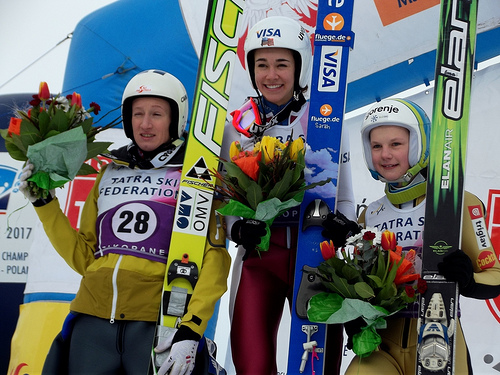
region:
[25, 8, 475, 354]
people are holding skis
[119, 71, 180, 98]
helmet on the head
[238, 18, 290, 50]
logo on the helmet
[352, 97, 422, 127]
logo on the helmet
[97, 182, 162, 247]
28 on the paper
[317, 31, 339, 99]
logo on the ski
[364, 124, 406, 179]
face of the boy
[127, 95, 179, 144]
face of the bow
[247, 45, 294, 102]
the boy is smiling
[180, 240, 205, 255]
the ski is yellow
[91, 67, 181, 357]
a person wearing a yellow jacket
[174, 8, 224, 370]
a yellow ski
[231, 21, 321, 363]
a lady wearing red pants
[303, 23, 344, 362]
a blue ski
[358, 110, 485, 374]
a girl wearing a white shirt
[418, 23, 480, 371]
a green ski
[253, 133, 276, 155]
a yellow flower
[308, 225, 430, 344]
a bouquet of flowers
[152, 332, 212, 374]
a white glove on the person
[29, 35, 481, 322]
three people holding flowers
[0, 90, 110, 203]
Flowers in the woman's right hand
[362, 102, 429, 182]
the woman is wearing a helmet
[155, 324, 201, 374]
The woman is wearing a glove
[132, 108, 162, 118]
The eyes of the woman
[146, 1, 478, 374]
Skis next to the women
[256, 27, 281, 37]
A Visa logo on the helmet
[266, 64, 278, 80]
The nose of the woman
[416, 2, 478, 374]
The ski is green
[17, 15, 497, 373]
Women posing for a picture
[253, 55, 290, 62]
The eyebrows of the woman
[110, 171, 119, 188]
The letter is black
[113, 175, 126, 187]
The letter is black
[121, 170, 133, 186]
The letter is black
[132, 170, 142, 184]
The letter is black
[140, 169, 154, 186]
The letter is black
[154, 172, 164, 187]
The letter is black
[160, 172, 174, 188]
The letter is black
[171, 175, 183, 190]
The letter is black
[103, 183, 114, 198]
The letter is black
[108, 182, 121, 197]
The letter is black